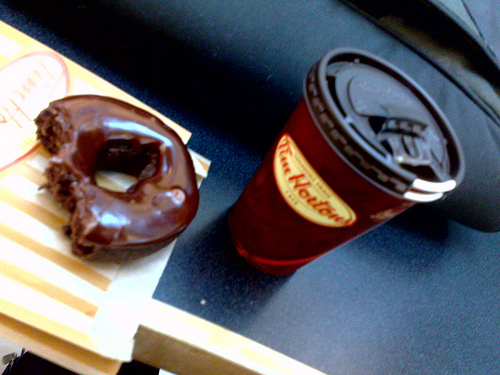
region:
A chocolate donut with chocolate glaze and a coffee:
[30, 33, 475, 309]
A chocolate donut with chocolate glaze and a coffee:
[30, 37, 473, 294]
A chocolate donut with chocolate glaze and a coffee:
[25, 38, 468, 295]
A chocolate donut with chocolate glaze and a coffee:
[26, 35, 466, 300]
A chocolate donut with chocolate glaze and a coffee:
[25, 40, 470, 300]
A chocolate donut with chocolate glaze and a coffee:
[30, 42, 470, 289]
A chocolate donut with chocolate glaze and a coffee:
[23, 42, 470, 283]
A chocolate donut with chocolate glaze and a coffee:
[27, 42, 468, 282]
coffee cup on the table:
[228, 77, 459, 284]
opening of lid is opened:
[362, 138, 452, 203]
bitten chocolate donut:
[1, 109, 101, 296]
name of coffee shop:
[278, 122, 360, 246]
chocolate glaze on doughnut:
[63, 106, 194, 232]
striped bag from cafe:
[6, 255, 116, 367]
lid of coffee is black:
[298, 64, 460, 191]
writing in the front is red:
[278, 138, 350, 234]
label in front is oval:
[281, 133, 356, 247]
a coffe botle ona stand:
[282, 80, 432, 281]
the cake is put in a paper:
[38, 82, 193, 327]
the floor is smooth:
[208, 47, 300, 177]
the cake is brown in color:
[88, 124, 218, 291]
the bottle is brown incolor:
[232, 43, 430, 305]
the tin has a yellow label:
[268, 107, 358, 257]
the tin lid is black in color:
[323, 43, 445, 260]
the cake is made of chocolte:
[61, 82, 189, 233]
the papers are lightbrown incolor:
[26, 217, 169, 374]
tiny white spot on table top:
[189, 292, 223, 318]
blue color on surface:
[304, 284, 432, 335]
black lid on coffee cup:
[300, 52, 485, 204]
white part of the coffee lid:
[392, 167, 462, 218]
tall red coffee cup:
[279, 141, 363, 298]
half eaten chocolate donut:
[31, 76, 207, 275]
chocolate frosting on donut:
[79, 105, 151, 155]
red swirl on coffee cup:
[253, 249, 342, 280]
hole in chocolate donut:
[94, 145, 149, 187]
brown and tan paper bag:
[21, 252, 151, 326]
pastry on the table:
[31, 59, 194, 260]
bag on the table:
[1, 18, 220, 373]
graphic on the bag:
[3, 43, 69, 187]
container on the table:
[230, 25, 470, 310]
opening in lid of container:
[400, 154, 445, 188]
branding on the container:
[273, 129, 348, 226]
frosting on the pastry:
[69, 100, 185, 227]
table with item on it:
[5, 20, 497, 361]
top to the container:
[320, 39, 464, 195]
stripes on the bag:
[10, 226, 60, 306]